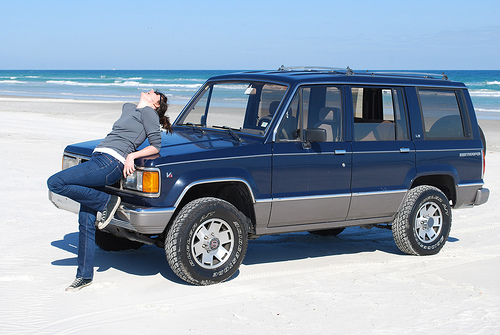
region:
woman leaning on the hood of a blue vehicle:
[45, 85, 173, 295]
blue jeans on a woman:
[45, 147, 122, 290]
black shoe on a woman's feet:
[97, 192, 126, 232]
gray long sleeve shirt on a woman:
[94, 101, 162, 158]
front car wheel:
[165, 194, 250, 284]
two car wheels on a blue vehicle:
[167, 180, 454, 287]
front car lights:
[121, 163, 163, 197]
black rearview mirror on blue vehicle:
[294, 124, 328, 145]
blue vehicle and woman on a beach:
[32, 60, 494, 295]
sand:
[78, 286, 498, 333]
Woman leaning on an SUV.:
[17, 86, 207, 256]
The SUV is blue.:
[61, 63, 491, 257]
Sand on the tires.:
[165, 190, 456, 263]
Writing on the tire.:
[176, 210, 256, 284]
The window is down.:
[343, 82, 405, 143]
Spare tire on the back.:
[425, 105, 489, 165]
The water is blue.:
[26, 49, 498, 93]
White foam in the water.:
[46, 66, 209, 91]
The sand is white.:
[294, 268, 479, 333]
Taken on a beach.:
[10, 37, 492, 331]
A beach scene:
[6, 9, 498, 321]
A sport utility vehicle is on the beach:
[40, 56, 494, 294]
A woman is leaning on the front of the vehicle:
[43, 85, 187, 302]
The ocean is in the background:
[6, 57, 133, 95]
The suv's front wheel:
[159, 190, 256, 292]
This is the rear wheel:
[394, 180, 457, 260]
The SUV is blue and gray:
[272, 155, 341, 220]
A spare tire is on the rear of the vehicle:
[429, 105, 491, 165]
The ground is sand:
[259, 269, 439, 327]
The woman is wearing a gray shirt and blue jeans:
[35, 85, 176, 295]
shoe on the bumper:
[97, 193, 122, 230]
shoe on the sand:
[62, 273, 94, 295]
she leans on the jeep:
[31, 60, 171, 287]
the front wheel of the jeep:
[164, 205, 248, 280]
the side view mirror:
[306, 123, 331, 146]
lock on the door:
[340, 161, 346, 167]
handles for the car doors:
[329, 144, 414, 161]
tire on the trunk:
[429, 109, 485, 155]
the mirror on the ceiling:
[242, 82, 260, 97]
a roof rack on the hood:
[273, 59, 458, 79]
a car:
[206, 90, 370, 327]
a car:
[185, 58, 298, 169]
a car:
[261, 192, 313, 257]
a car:
[237, 152, 332, 324]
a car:
[204, 101, 258, 209]